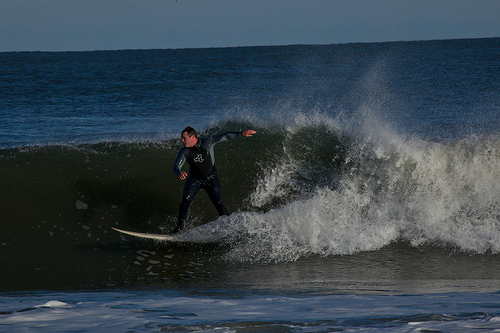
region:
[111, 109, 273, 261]
man riding a surfboard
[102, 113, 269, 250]
man on a surfboard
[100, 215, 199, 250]
white surboard in the water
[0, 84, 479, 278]
large wave in the ocean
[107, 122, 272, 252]
man wearing a wet suit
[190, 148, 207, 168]
logo on a wet suit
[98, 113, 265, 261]
man riding a surfboard on a wave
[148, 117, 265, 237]
man with brown hair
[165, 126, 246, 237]
grey and black wet suit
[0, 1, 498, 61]
clear blue sky with no clouds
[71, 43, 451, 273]
a man is surfing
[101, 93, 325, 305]
a man is surfing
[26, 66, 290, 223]
a man is surfing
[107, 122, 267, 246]
A proficient surfer riding the waves.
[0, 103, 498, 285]
A big wave of a green color.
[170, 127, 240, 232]
The guy is wearing a black wetsuit.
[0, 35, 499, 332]
The vast ocean in which the man is surfing.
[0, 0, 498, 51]
A beautiful dark dark blue sky above the sky.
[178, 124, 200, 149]
The head of a white surfer.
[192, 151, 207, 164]
The logo of the brand wetsuit.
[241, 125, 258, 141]
The left hand of a white surfer.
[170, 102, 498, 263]
The part of the waves propelling the surfer.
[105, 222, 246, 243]
The white surfboard under the surfer's foot.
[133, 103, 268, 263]
the man is surfing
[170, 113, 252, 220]
man wearing a wet suit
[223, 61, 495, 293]
the waves are white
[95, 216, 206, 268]
the surfboard is white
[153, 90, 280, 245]
man is standing on surfboard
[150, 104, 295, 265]
the man is wet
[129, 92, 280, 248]
the man is alone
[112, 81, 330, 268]
waves are splashing man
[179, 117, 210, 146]
man's hair is black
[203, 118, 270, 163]
man's left arm is stretched out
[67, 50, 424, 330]
a surfer in the water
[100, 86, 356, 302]
a surfer on a wave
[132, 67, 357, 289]
a surfer riding a wave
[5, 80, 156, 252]
a body of water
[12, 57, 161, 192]
a body of blue water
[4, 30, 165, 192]
a body of water with waves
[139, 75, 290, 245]
a man surfing on a surfboard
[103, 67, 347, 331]
a man with arms out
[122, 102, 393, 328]
a man in a wetsuit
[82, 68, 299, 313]
a man wearing a wet suit